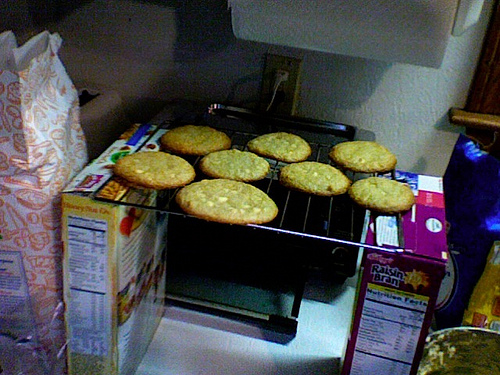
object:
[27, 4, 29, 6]
bike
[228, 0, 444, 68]
towels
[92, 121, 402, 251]
rack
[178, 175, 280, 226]
cookie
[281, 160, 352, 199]
cookie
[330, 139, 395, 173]
cookie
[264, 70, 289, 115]
plug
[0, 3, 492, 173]
wall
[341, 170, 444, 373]
box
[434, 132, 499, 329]
bag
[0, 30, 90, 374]
bag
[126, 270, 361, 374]
counter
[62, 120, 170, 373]
box